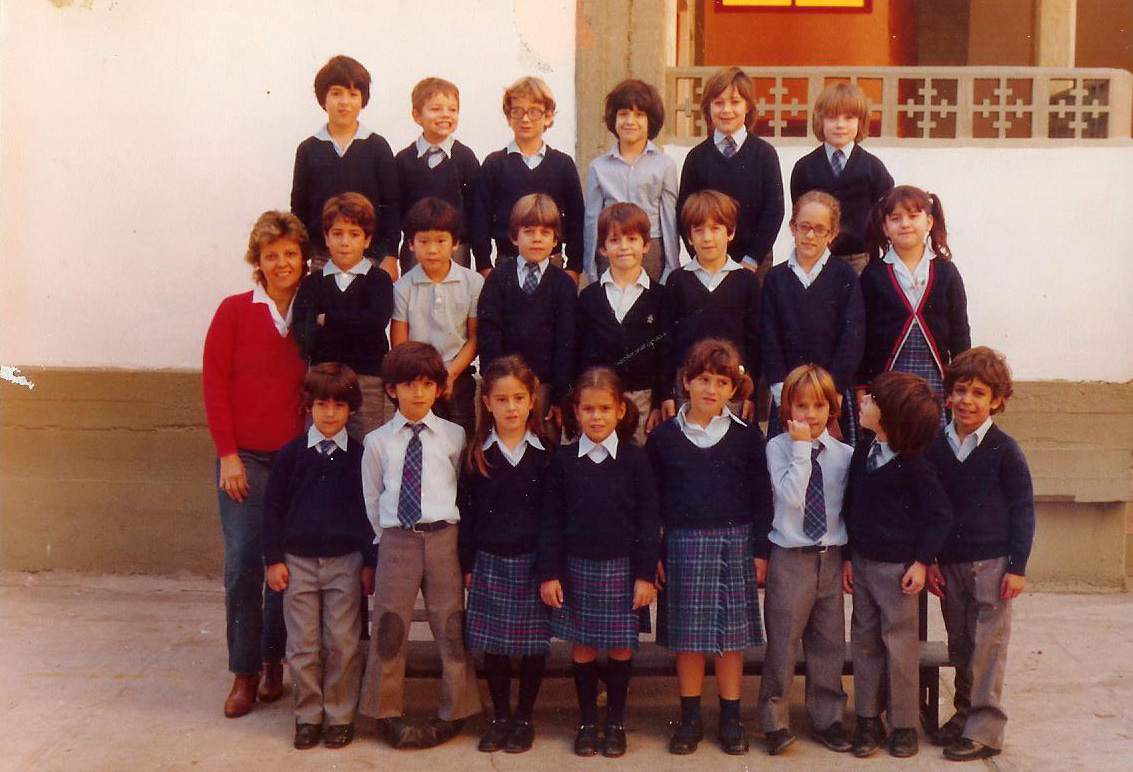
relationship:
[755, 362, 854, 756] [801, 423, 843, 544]
kid wearing neck tie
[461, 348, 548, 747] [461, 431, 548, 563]
girl wearing sweater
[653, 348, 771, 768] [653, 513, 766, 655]
girl with skirt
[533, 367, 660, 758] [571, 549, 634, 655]
kid with skirt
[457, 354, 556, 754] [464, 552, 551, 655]
girl with skirt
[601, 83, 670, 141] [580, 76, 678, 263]
hair of boy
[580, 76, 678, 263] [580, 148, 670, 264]
boy with dress shirt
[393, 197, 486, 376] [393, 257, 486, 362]
boy with shirt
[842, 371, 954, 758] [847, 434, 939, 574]
kid wearing sweater